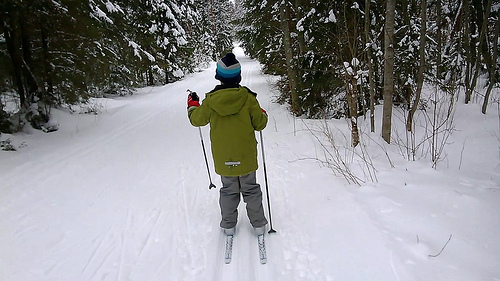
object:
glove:
[187, 92, 201, 110]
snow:
[0, 100, 59, 148]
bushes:
[253, 0, 494, 113]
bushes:
[4, 3, 161, 96]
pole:
[188, 92, 216, 190]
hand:
[187, 91, 200, 111]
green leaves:
[86, 45, 103, 54]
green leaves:
[304, 11, 330, 76]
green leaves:
[261, 54, 290, 75]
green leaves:
[143, 15, 172, 31]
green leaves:
[249, 13, 281, 46]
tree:
[0, 0, 52, 132]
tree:
[61, 0, 117, 103]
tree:
[382, 0, 395, 145]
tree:
[281, 0, 304, 116]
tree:
[134, 0, 190, 85]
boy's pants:
[218, 173, 268, 228]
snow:
[37, 174, 188, 279]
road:
[3, 45, 311, 279]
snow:
[274, 114, 498, 279]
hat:
[213, 53, 242, 83]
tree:
[460, 1, 483, 105]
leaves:
[395, 40, 416, 73]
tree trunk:
[382, 4, 395, 142]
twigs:
[299, 118, 336, 159]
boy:
[184, 53, 276, 237]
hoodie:
[187, 85, 268, 177]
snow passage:
[94, 58, 262, 278]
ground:
[1, 42, 498, 279]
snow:
[67, 126, 171, 166]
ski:
[224, 232, 233, 264]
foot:
[219, 226, 236, 235]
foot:
[250, 222, 267, 235]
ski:
[257, 215, 267, 264]